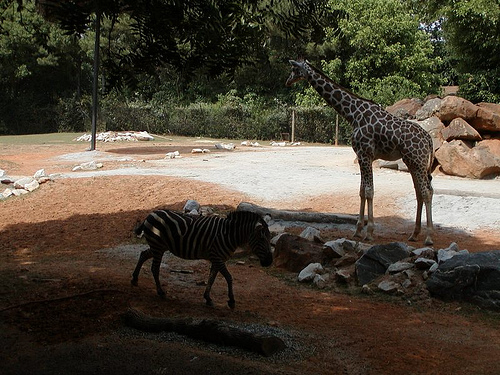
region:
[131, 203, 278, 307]
Zebra walking by rocks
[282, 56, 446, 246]
Giraffe standing next to rocks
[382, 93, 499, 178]
Rocks in the pen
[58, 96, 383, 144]
Fence enclosing pen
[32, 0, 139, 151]
Tree the giraffe can eat from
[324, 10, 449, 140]
Tree next to the pen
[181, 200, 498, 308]
Rocks next to giraffe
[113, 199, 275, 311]
the zebra is walking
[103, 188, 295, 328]
the zebra is walking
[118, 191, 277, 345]
the zebra is walking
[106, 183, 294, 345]
the zebra is walking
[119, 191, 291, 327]
the zebra is walking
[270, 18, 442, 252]
the giraffe is brown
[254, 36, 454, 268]
the giraffe is brown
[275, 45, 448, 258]
the giraffe is brown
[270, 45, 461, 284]
the giraffe is brown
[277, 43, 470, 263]
the giraffe is brown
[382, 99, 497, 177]
pile of rocks in enclosure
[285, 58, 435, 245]
side of standing giraffe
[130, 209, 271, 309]
side of walking zebra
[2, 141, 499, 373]
dirt of zoo enclosure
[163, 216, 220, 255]
stripes on zebra torso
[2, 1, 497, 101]
green leaves on trees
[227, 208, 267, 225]
mane on zebra neck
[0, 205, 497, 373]
shadow on ground of enclosure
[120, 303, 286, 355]
log on ground surface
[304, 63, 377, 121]
long neck of giraffe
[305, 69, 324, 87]
Brown spots on a giraffe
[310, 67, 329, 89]
Brown spots on a giraffe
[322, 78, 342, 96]
Brown spots on a giraffe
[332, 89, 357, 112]
Brown spots on a giraffe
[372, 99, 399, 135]
Brown spots on a giraffe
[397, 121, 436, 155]
Brown spots on a giraffe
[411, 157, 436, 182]
Brown spots on a giraffe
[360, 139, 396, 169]
Brown spots on a giraffe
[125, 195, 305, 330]
This is a zebra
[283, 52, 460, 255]
This is a giraffe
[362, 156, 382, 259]
Leg of a giraffe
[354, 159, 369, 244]
Leg of a giraffe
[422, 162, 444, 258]
Leg of a giraffe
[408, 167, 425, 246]
Leg of a giraffe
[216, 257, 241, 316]
Leg of a zebra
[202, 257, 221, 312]
Leg of a zebra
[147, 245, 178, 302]
Leg of a zebra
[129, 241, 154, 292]
Leg of a zebra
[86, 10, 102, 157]
vertical pole in dirt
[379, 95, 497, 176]
pile of rocks in enclosure